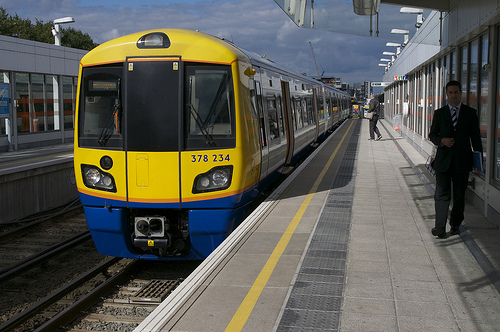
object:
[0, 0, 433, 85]
sky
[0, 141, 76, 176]
platform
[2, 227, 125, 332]
train tracks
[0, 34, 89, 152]
building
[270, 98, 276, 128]
glass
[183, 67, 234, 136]
window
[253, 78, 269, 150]
window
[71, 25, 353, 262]
train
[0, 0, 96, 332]
left